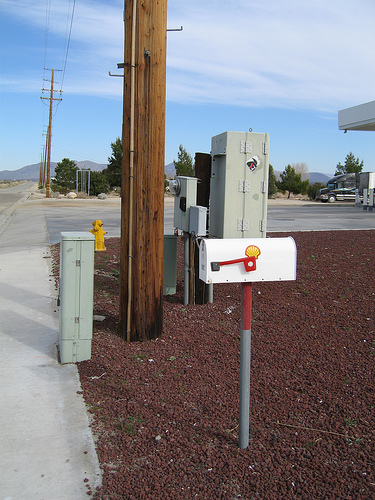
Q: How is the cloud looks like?
A: High.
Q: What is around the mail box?
A: Gravel.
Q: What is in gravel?
A: Utility pole.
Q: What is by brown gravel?
A: Cement sidewalk.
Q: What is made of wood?
A: A pole.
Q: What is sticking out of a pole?
A: Metal hooks.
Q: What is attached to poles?
A: Electrical wires.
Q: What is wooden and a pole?
A: Electrical pole.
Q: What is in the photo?
A: Utility equipment.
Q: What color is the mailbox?
A: White.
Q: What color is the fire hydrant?
A: Yellow.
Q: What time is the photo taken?
A: Daytime.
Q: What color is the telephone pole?
A: Brown.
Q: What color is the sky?
A: Blue.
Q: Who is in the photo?
A: No one.